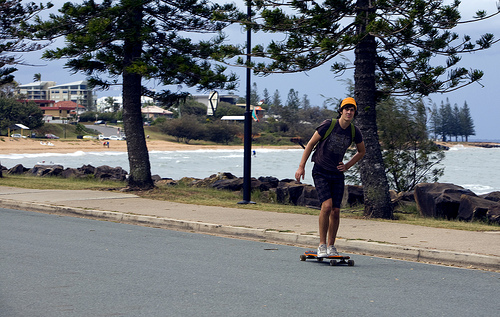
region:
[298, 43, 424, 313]
Man on a skateboard.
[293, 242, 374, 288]
White shoes on the skateboard.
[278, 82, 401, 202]
Man with an orange hat.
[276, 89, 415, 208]
Man with a backpack.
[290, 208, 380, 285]
Man wearing white shoes.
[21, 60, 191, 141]
Buildings in the background.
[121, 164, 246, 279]
Sidewalk on the road.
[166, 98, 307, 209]
Rocks by the water.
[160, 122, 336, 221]
Water in the background.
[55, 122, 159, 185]
Sandy beach by the water.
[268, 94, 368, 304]
a man on a skateboard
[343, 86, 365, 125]
a man wearing a yellow hat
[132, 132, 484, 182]
a body of water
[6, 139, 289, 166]
a beach next to the ocean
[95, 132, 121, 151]
people standing on a beach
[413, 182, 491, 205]
a large rock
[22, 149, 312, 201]
several large rocks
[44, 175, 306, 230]
a concrete sidewalk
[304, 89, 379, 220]
a man with his hand on his hip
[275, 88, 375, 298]
a man wearing white tennis shoes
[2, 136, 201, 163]
Sandy beach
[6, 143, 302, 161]
Whitecapped waves washing up on a beach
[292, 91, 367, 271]
Man on a skateboard in the street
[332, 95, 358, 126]
Yellow cap on a man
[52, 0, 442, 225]
Tall pine trees next to the sidewalk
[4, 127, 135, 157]
Cars parked at the beach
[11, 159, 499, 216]
Rocks along the shoreline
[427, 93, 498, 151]
A stand of pine trees in the distance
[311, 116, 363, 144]
Green straps of a backpack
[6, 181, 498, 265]
Concrete sidewalk and curb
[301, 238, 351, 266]
orange skate board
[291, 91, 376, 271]
guy posing on orange skate board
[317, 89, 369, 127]
guy is wearing an orange hat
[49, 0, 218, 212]
evergreen tree in grassy area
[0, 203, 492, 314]
skate boarder riding on pavement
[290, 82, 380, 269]
skateboarder has his right hand on hips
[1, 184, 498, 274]
sidewalk is next to skateboarder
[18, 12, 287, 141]
many houses in the background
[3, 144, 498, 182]
body of water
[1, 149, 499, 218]
rockery hold up hill next to ocean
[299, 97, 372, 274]
man wearing an orange hat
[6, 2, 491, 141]
bright blue sky with no clouds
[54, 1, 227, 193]
bottom of a pine tree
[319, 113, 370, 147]
green straps of a backpack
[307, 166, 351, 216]
checkered shorts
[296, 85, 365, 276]
man riding a skateboard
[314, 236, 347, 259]
bright white sneakers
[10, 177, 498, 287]
sidewalk that runs along the road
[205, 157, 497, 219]
dark grey rocks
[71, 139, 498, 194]
very light blue ocean water